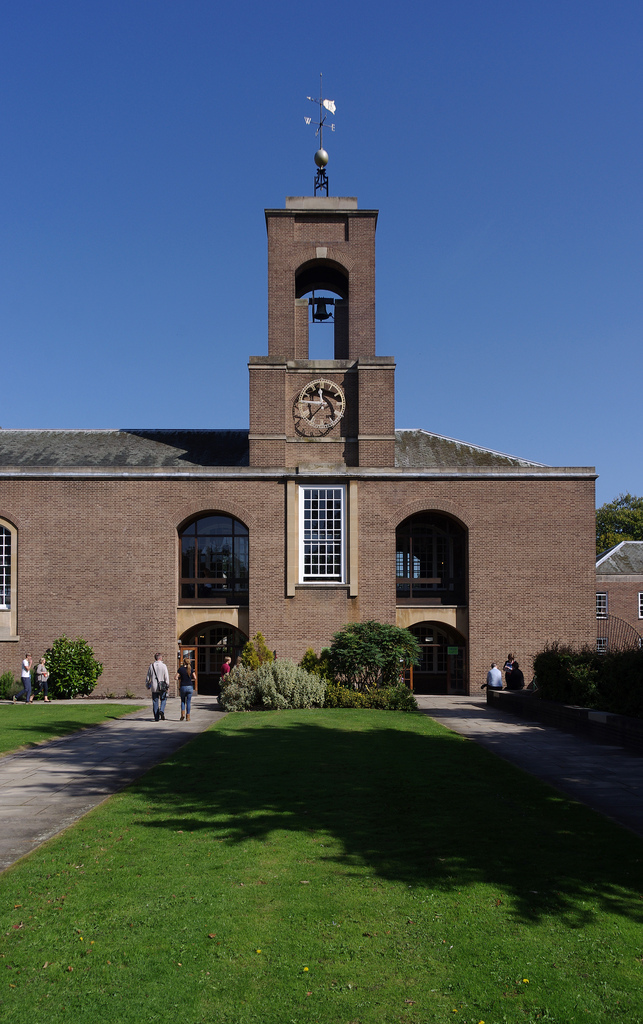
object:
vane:
[304, 72, 337, 146]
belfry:
[264, 72, 396, 367]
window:
[304, 488, 344, 584]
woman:
[174, 657, 197, 720]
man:
[145, 652, 170, 720]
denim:
[180, 686, 193, 714]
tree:
[242, 633, 275, 669]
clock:
[298, 377, 347, 428]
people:
[145, 654, 170, 722]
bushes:
[217, 621, 422, 717]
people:
[481, 660, 504, 692]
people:
[13, 651, 31, 705]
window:
[175, 507, 249, 606]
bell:
[314, 304, 329, 322]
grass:
[0, 704, 643, 1024]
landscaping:
[220, 621, 423, 711]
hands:
[301, 389, 327, 410]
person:
[220, 655, 231, 679]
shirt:
[221, 663, 231, 680]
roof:
[0, 427, 595, 481]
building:
[0, 197, 598, 698]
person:
[13, 652, 33, 706]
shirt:
[21, 655, 31, 677]